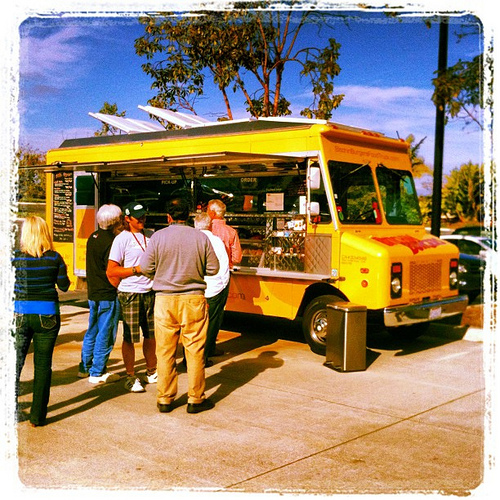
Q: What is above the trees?
A: The sky.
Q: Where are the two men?
A: Outside the truck.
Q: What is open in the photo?
A: The food truck.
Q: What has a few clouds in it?
A: The blue sky.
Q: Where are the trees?
A: Behind the truck.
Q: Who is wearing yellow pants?
A: The man.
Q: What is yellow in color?
A: The truck.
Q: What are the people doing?
A: Waiting.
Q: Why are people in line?
A: To order food.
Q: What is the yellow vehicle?
A: Food truck.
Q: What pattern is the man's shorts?
A: Plaid.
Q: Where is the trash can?
A: Near the front of the food truck.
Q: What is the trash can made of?
A: Metal.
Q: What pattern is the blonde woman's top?
A: Striped.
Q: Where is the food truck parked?
A: On the sidewalk.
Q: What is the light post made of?
A: Metal.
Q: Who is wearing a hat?
A: The guy with plaid shorts.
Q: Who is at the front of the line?
A: The man with the pink shirt.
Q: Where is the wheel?
A: On the truck.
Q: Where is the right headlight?
A: On the truck.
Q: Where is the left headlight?
A: On the truck.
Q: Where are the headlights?
A: On the truck.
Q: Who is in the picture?
A: People.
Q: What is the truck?
A: A food truck.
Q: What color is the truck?
A: Yellow.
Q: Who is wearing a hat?
A: The boy.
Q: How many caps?
A: One.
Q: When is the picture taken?
A: Daytime.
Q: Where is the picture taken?
A: On the street.